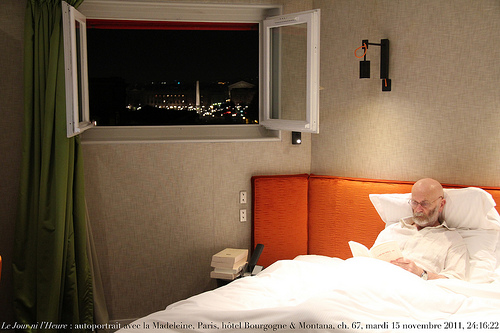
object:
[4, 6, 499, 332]
room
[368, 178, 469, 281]
man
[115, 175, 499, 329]
bed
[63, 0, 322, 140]
window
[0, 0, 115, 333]
curtain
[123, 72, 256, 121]
city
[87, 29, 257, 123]
outside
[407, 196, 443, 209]
spectacles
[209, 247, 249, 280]
books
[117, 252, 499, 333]
bed coverings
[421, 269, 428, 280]
watch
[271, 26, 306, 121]
glass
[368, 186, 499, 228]
pillow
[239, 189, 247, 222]
outlets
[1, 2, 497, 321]
wall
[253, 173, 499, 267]
back of bed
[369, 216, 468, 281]
shirt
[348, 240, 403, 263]
book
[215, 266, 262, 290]
side table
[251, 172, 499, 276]
headboard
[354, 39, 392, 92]
light